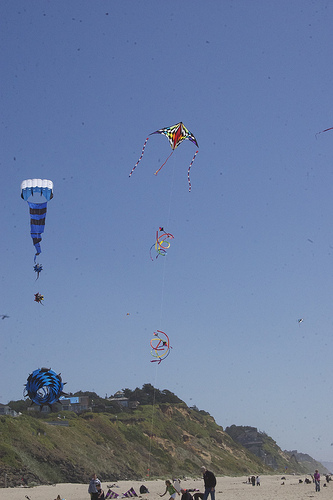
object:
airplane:
[297, 318, 303, 323]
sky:
[0, 0, 333, 411]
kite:
[121, 487, 138, 499]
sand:
[0, 474, 333, 500]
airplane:
[129, 121, 200, 192]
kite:
[150, 329, 173, 364]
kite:
[23, 366, 70, 412]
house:
[52, 395, 89, 413]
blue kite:
[15, 168, 55, 292]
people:
[314, 469, 321, 492]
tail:
[153, 151, 173, 176]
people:
[255, 475, 260, 486]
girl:
[159, 479, 180, 498]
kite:
[149, 225, 174, 261]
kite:
[129, 121, 200, 192]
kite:
[33, 263, 44, 282]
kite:
[34, 291, 45, 306]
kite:
[0, 315, 10, 321]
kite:
[298, 318, 304, 323]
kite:
[315, 127, 333, 140]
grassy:
[118, 424, 170, 458]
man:
[200, 465, 216, 498]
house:
[0, 405, 17, 416]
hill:
[0, 382, 329, 493]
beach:
[0, 471, 333, 500]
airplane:
[20, 178, 54, 264]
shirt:
[203, 470, 216, 489]